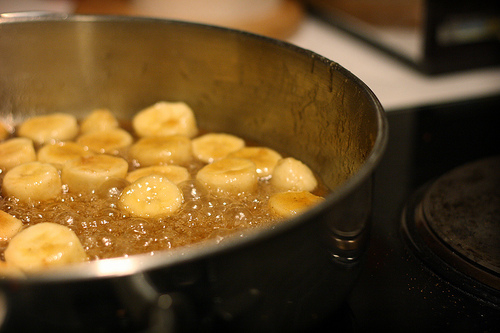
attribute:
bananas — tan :
[15, 117, 236, 208]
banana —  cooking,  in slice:
[3, 159, 60, 203]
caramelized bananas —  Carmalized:
[2, 100, 322, 272]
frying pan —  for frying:
[1, 8, 391, 329]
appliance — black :
[300, 0, 499, 75]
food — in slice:
[196, 154, 261, 191]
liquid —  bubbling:
[1, 121, 333, 263]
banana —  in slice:
[129, 97, 199, 140]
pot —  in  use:
[7, 8, 404, 288]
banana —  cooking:
[189, 127, 308, 202]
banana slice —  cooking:
[120, 170, 181, 219]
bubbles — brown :
[23, 183, 276, 270]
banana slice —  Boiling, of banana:
[206, 160, 256, 196]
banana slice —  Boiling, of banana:
[241, 142, 282, 173]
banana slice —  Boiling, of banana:
[66, 147, 116, 184]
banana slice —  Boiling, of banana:
[192, 137, 232, 157]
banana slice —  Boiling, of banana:
[6, 220, 93, 272]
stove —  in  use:
[230, 90, 497, 324]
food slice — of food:
[119, 177, 183, 222]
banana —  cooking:
[27, 112, 228, 179]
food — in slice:
[118, 172, 185, 221]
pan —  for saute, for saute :
[3, 14, 390, 306]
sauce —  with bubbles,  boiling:
[81, 213, 261, 261]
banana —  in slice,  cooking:
[118, 174, 181, 219]